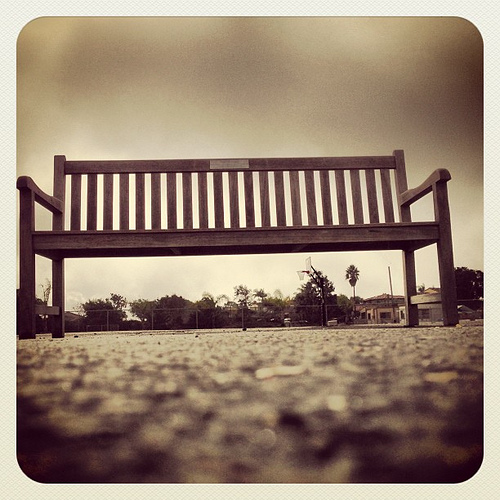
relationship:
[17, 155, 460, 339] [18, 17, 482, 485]
bench at park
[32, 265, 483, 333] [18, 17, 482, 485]
trees at park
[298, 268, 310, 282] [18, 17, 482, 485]
basketball hoop at park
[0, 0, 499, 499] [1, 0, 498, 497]
picture in black and white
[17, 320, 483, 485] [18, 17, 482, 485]
ground at park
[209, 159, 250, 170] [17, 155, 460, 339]
label on bench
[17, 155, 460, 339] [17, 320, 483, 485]
bench on ground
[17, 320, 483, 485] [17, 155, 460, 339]
ground under bench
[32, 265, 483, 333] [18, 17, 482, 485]
trees around park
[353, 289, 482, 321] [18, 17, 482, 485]
structures outside of park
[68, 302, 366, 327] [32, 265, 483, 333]
fence near trees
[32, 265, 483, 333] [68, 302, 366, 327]
trees near fence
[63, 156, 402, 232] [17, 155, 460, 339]
slats on bench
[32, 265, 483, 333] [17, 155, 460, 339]
trees behind bench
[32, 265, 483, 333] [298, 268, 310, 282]
trees near basketball hoop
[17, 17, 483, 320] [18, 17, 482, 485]
sky above park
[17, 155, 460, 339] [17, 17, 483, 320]
bench under sky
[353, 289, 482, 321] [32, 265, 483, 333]
structures near trees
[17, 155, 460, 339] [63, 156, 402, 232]
bench has slats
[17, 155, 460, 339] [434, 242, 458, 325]
bench has a leg